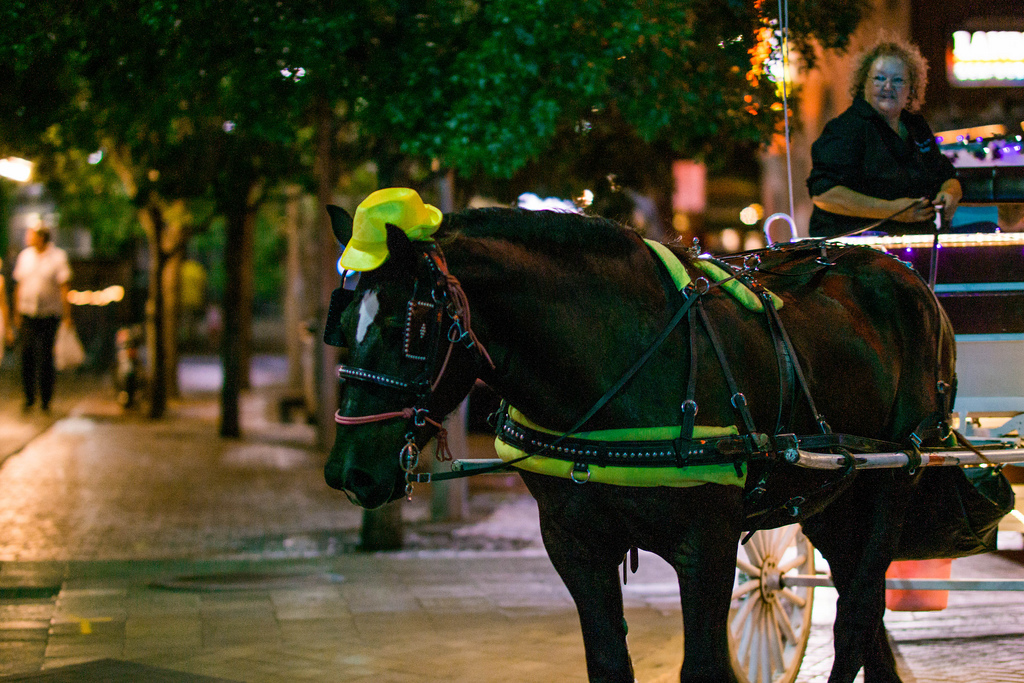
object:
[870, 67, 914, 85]
glasses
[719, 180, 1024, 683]
carriage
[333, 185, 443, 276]
hat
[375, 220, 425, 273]
ear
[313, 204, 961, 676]
horse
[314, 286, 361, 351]
eyes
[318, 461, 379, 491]
nose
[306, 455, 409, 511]
mouth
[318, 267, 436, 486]
face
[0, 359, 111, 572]
sidewalk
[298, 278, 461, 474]
bridle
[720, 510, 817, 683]
wheel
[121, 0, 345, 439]
trees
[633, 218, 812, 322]
trim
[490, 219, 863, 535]
straps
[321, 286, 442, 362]
blinders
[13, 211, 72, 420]
person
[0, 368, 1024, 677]
street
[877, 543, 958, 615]
container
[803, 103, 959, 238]
shirt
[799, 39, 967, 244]
woman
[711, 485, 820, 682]
carriage wheel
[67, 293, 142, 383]
bag